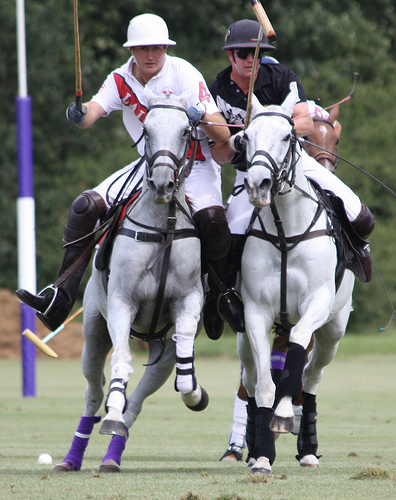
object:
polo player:
[202, 17, 375, 341]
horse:
[221, 87, 355, 476]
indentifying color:
[14, 96, 37, 196]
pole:
[14, 1, 35, 402]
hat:
[120, 12, 179, 50]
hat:
[220, 19, 277, 52]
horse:
[295, 101, 344, 195]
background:
[0, 1, 391, 457]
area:
[0, 352, 394, 496]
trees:
[1, 3, 392, 325]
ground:
[1, 351, 390, 499]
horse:
[50, 86, 208, 472]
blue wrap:
[63, 414, 98, 474]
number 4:
[198, 80, 214, 105]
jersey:
[92, 53, 224, 164]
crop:
[0, 141, 135, 289]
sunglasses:
[234, 47, 263, 59]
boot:
[13, 282, 74, 334]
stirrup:
[31, 283, 62, 319]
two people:
[14, 12, 375, 342]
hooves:
[248, 351, 277, 475]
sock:
[293, 390, 321, 460]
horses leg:
[294, 325, 342, 468]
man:
[13, 12, 229, 341]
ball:
[34, 450, 53, 476]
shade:
[0, 445, 249, 478]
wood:
[242, 0, 278, 136]